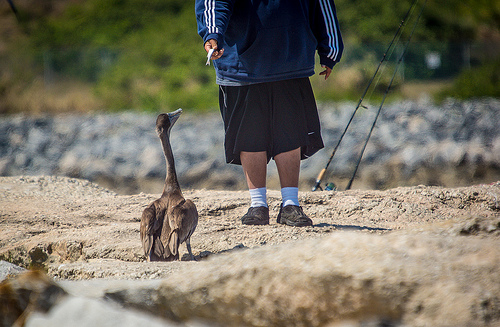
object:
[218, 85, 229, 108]
pocket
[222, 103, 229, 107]
part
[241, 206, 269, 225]
shoe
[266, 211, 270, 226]
edge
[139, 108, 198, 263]
duck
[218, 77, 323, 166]
shorts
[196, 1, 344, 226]
person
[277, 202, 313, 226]
shoe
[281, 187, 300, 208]
sock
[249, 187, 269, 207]
sock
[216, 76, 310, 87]
undershirt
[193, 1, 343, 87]
sweatshirt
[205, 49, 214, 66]
fish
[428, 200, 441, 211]
dirt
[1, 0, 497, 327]
ground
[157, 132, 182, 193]
neck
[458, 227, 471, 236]
rock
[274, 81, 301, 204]
leg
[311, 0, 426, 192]
fishing gear